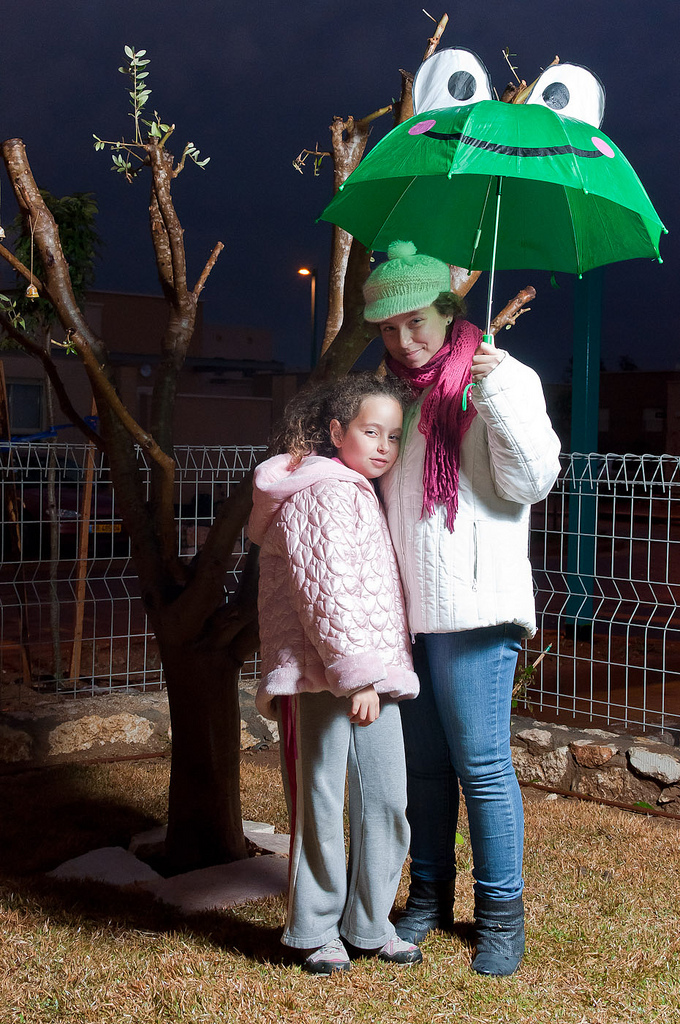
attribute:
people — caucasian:
[249, 255, 566, 973]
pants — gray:
[276, 705, 410, 944]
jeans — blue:
[431, 642, 540, 894]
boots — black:
[472, 886, 523, 971]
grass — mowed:
[101, 893, 255, 1020]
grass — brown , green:
[113, 970, 188, 1014]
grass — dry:
[51, 907, 239, 1001]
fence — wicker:
[555, 457, 677, 729]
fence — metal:
[527, 446, 626, 632]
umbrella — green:
[313, 46, 663, 372]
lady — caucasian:
[362, 243, 566, 974]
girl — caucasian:
[227, 376, 424, 976]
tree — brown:
[2, 10, 588, 862]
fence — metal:
[4, 434, 678, 744]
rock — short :
[0, 680, 679, 818]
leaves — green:
[85, 42, 217, 182]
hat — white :
[352, 233, 454, 327]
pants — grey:
[267, 691, 420, 953]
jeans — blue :
[406, 620, 535, 902]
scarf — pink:
[381, 295, 514, 609]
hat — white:
[363, 231, 456, 323]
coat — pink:
[248, 452, 417, 696]